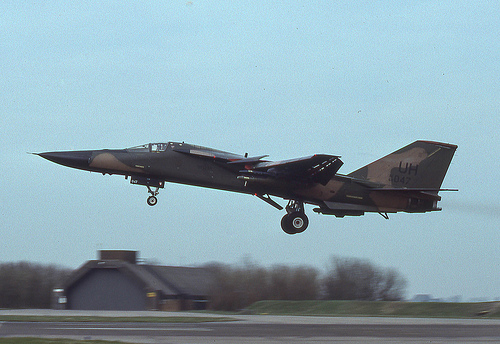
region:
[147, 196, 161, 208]
the small wheel of a plane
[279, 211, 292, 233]
the small wheel of a plane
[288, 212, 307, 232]
the small wheel of a plane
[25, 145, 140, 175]
the pointed nose of the plane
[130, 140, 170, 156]
the cockpit of the plane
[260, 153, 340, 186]
the wing of the plane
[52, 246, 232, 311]
the large building in the background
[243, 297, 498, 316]
the long mound of grass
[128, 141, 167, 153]
the window of the plane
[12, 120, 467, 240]
an aircraft in the air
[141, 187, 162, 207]
front wheel of aircraft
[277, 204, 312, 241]
back wheel of aircraft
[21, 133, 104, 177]
nose of aircraft is pointy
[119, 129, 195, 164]
cockpit of aircraft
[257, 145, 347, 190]
right wing of plane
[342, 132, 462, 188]
vertical stabilizer of plane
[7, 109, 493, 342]
a plane above the ground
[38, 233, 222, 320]
a building with a big door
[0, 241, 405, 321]
trees around a building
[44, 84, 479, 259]
military jet in air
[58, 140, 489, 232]
military jet fighter in air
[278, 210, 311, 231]
black landing wheels of plane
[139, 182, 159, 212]
front landing wheels of plane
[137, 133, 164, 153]
cockpit on front of plane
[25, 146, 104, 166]
black tip to plane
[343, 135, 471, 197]
green and tan tail fin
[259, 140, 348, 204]
side wing of plane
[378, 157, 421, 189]
black writing on wing of plane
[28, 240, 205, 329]
large building in background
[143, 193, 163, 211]
Small wheel of a jet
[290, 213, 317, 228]
Small wheel of a jet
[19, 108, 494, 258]
JEt in the air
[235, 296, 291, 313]
Small patch of green grass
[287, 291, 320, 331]
Small patch of green grass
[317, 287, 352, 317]
Small patch of green grass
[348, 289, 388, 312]
Small patch of green grass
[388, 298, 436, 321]
Small patch of green grass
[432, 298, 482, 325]
Small patch of green grass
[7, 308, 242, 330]
Small patch of green grass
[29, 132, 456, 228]
little airplane in sky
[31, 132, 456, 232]
little camouflage airplane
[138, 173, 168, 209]
front wheel of little jetplane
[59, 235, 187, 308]
small house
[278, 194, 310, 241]
two black back wheels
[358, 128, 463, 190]
camouflaged empennage of jetplane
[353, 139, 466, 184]
camouflaged tail of jetplane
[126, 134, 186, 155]
pilothouse on camouflage jetplane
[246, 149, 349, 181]
small left wing of jetplane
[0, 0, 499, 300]
light blue and clear sky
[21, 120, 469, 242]
a jet taken off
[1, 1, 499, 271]
a blue sky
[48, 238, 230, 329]
a gray building in the background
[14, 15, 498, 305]
a scene during the day time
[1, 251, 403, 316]
some trees in the background